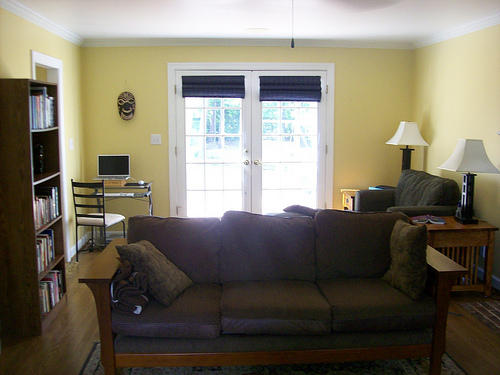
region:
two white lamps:
[346, 97, 496, 223]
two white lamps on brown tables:
[353, 105, 498, 276]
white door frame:
[151, 60, 397, 237]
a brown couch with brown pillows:
[82, 190, 485, 367]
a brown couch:
[76, 190, 475, 363]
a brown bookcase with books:
[0, 65, 103, 342]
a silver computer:
[66, 137, 191, 264]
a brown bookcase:
[2, 77, 79, 324]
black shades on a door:
[160, 62, 387, 227]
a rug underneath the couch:
[56, 210, 478, 373]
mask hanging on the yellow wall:
[108, 80, 140, 125]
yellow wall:
[339, 53, 412, 118]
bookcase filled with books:
[0, 77, 68, 347]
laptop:
[89, 149, 144, 183]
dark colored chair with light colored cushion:
[68, 177, 125, 252]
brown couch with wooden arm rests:
[89, 211, 457, 363]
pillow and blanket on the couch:
[117, 236, 213, 315]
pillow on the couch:
[380, 218, 427, 300]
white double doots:
[163, 62, 338, 204]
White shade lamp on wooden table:
[438, 137, 499, 226]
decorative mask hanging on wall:
[107, 75, 144, 130]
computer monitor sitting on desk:
[89, 144, 136, 189]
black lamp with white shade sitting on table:
[381, 103, 426, 190]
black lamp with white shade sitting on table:
[438, 131, 494, 241]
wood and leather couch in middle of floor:
[64, 201, 496, 373]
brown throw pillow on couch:
[105, 226, 209, 321]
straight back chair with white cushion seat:
[58, 173, 139, 277]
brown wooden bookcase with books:
[3, 66, 83, 346]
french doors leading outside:
[163, 53, 360, 233]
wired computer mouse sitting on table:
[127, 174, 147, 197]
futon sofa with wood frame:
[91, 201, 468, 371]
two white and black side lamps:
[386, 123, 498, 204]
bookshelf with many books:
[18, 72, 81, 323]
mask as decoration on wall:
[101, 76, 150, 142]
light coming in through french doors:
[163, 66, 335, 221]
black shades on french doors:
[178, 71, 334, 113]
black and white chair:
[61, 174, 120, 255]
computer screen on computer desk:
[86, 155, 163, 247]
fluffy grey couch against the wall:
[349, 168, 461, 227]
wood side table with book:
[416, 212, 493, 304]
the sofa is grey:
[78, 209, 467, 374]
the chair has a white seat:
[78, 205, 122, 235]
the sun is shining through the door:
[177, 72, 327, 224]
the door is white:
[163, 57, 336, 229]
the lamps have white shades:
[383, 119, 498, 185]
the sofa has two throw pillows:
[109, 218, 436, 305]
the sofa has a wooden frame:
[73, 231, 468, 373]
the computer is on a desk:
[81, 177, 164, 249]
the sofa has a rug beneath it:
[72, 330, 470, 374]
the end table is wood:
[411, 206, 498, 309]